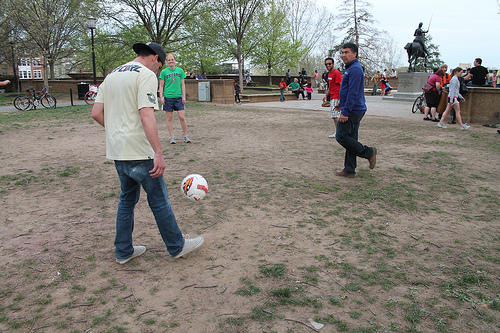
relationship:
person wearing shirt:
[174, 53, 191, 143] [157, 67, 186, 99]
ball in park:
[179, 172, 209, 203] [0, 66, 416, 330]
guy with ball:
[91, 41, 203, 261] [181, 172, 208, 199]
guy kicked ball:
[91, 41, 203, 261] [181, 172, 208, 199]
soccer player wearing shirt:
[153, 48, 198, 147] [162, 66, 184, 99]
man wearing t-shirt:
[321, 56, 346, 139] [324, 68, 341, 98]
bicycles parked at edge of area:
[0, 80, 65, 120] [30, 111, 426, 329]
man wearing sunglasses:
[321, 56, 346, 139] [314, 48, 339, 77]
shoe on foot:
[168, 235, 209, 256] [162, 224, 218, 274]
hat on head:
[131, 40, 168, 65] [127, 29, 173, 88]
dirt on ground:
[1, 98, 498, 329] [2, 87, 496, 327]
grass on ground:
[235, 157, 399, 248] [12, 115, 392, 322]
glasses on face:
[324, 64, 335, 68] [322, 58, 336, 71]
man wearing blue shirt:
[321, 38, 380, 176] [331, 61, 418, 118]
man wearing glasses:
[317, 56, 347, 140] [325, 62, 334, 66]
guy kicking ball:
[91, 41, 207, 265] [179, 172, 209, 202]